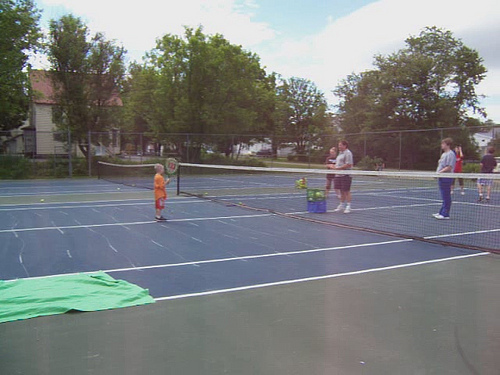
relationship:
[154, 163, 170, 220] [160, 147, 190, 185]
boy holding racket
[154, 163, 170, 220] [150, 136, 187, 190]
boy holding racket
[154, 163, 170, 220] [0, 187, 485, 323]
boy on court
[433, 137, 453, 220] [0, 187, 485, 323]
adults on court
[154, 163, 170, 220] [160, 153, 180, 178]
boy holding racquet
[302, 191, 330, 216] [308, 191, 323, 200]
basket of balls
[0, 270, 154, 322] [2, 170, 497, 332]
blanket lying on tennis court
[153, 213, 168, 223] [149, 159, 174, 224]
shoe on boy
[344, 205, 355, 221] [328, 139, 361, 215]
shoe on man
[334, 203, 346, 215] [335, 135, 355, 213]
shoe on man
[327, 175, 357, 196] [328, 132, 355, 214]
shorts on man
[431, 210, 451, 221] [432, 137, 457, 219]
shoes on woman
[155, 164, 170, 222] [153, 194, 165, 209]
boy wearing red shorts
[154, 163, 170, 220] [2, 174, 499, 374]
boy standing on tennis court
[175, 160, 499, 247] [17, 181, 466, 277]
net on tennis court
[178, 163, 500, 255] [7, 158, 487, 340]
net on tennis court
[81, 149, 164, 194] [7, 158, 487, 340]
net on tennis court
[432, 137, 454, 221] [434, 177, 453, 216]
man wearing jeans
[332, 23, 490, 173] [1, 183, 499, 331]
trees near court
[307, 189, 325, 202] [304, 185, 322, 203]
basket of balls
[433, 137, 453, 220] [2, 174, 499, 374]
adults standing on tennis court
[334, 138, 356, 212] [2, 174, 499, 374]
adults standing on tennis court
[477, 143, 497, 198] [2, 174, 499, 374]
adults standing on tennis court